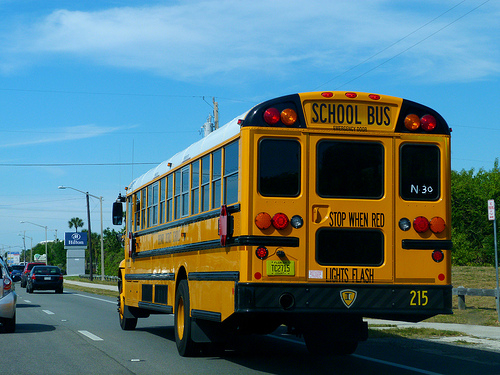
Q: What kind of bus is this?
A: School.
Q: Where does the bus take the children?
A: School.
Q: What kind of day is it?
A: Sunny.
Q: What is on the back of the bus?
A: Emergency door.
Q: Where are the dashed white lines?
A: On the road.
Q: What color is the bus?
A: Yellow.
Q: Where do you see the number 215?
A: On the bumper of the bus.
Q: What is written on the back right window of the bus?
A: N 30.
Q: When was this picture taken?
A: During daylight.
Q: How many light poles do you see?
A: 4.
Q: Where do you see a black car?
A: In front of the bus.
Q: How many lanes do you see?
A: 2.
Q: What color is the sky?
A: Blue.